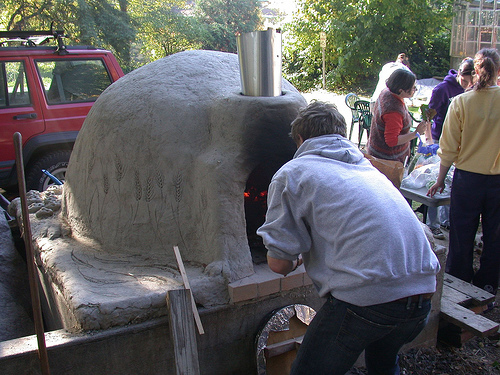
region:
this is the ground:
[423, 356, 499, 371]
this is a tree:
[303, 0, 443, 50]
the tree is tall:
[341, 2, 372, 83]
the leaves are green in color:
[339, 3, 420, 51]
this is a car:
[1, 29, 131, 186]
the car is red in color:
[47, 108, 71, 129]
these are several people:
[268, 54, 499, 366]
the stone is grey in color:
[118, 115, 182, 182]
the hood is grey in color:
[319, 169, 356, 214]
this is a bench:
[444, 285, 476, 318]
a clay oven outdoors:
[36, 13, 304, 287]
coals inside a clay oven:
[240, 166, 271, 222]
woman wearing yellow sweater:
[419, 43, 498, 276]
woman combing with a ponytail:
[447, 40, 497, 116]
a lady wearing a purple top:
[426, 54, 479, 143]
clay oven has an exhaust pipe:
[59, 19, 293, 279]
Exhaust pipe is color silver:
[226, 20, 293, 105]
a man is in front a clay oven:
[163, 11, 460, 371]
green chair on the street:
[340, 82, 378, 142]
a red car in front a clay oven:
[0, 19, 133, 202]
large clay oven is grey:
[50, 34, 307, 276]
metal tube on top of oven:
[231, 22, 296, 113]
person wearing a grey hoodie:
[262, 100, 434, 330]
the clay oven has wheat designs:
[106, 154, 202, 238]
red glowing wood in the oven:
[238, 157, 268, 224]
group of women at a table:
[369, 57, 499, 208]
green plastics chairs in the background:
[344, 91, 370, 135]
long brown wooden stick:
[8, 129, 60, 371]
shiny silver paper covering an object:
[255, 302, 308, 354]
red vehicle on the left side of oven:
[0, 44, 110, 186]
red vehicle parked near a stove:
[1, 25, 141, 215]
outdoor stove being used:
[13, 39, 403, 366]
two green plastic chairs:
[339, 87, 377, 141]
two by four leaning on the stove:
[163, 282, 203, 374]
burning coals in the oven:
[236, 182, 277, 205]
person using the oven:
[248, 85, 443, 373]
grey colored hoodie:
[243, 127, 447, 309]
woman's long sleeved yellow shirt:
[431, 82, 498, 187]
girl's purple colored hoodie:
[423, 62, 468, 161]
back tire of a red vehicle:
[22, 137, 88, 202]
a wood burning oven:
[55, 39, 298, 274]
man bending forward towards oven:
[214, 95, 439, 367]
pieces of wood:
[160, 233, 211, 372]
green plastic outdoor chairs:
[336, 82, 373, 147]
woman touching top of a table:
[410, 45, 497, 210]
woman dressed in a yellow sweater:
[436, 46, 498, 174]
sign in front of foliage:
[287, 4, 397, 91]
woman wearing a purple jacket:
[427, 55, 472, 140]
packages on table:
[402, 148, 454, 221]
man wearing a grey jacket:
[251, 99, 439, 305]